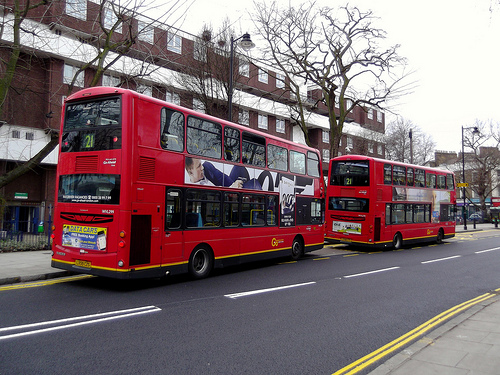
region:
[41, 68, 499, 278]
two double decker buses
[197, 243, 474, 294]
white dashed lane dividers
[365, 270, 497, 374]
a cement side walk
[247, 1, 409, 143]
a bare tree with curved branches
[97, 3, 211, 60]
a row of windows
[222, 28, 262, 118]
a street lamp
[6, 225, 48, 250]
a smallblack fence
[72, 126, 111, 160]
route number 21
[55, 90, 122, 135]
the rear window of a bus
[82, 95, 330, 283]
red double deck bus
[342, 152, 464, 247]
red double deck bus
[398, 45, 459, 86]
white clouds in blue sky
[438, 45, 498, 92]
white clouds in blue sky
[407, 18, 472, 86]
white clouds in blue sky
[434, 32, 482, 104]
white clouds in blue sky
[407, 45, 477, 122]
white clouds in blue sky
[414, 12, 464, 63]
white clouds in blue sky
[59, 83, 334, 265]
first red and black bus in line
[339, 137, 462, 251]
second red bus in line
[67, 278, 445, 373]
black asphalt road with white lines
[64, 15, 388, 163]
long brick building with white trim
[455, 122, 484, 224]
light post behind last bus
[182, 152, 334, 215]
007 advertisement on first bus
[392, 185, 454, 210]
white advertisement on second bus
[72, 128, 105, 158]
green number 21 on first bus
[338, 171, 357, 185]
green 21 on second bus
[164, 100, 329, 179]
top line of windows on first bus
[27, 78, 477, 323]
two double level buses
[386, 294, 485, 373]
a yellow line painted on a street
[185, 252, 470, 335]
white lines painted on a street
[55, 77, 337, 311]
a red two level bus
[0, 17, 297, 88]
a red brick building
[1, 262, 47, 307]
a curb next to a street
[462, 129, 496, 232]
a tree with no leaves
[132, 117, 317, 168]
a row of windows on a bus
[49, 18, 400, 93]
several trees with no leaves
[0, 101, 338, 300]
a bus parked next to a curb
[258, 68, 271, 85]
window on the building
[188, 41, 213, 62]
window on the building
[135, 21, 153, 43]
window on the building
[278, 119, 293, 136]
window on the building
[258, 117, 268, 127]
window on the building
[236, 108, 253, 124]
window on the building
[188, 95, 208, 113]
window on the building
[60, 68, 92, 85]
window on the building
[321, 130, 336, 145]
window on the building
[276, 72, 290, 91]
window on the building